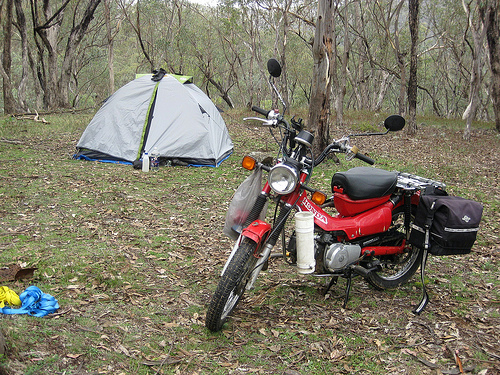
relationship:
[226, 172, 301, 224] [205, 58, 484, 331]
bag hanging on motorcycle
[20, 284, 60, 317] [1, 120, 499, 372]
item in grass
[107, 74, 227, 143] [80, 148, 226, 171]
gray tent on blue tarp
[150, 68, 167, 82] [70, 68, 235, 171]
glove on top of tent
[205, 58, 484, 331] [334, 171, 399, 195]
motorcycle with seat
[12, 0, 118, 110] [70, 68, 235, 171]
tree behind tent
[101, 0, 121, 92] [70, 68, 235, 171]
tree behind tent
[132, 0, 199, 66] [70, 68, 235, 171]
tree behind tent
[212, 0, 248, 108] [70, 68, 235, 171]
tree behind tent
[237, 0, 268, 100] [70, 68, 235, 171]
tree behind tent